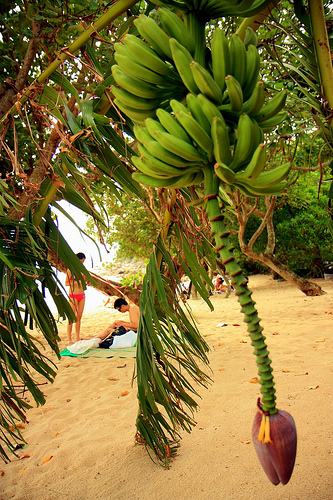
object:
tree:
[0, 0, 333, 319]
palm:
[149, 187, 175, 297]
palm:
[0, 0, 139, 128]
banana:
[154, 130, 208, 166]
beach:
[1, 270, 331, 498]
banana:
[235, 161, 292, 189]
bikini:
[68, 294, 85, 302]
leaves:
[194, 374, 206, 381]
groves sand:
[0, 275, 333, 498]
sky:
[124, 131, 135, 143]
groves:
[249, 377, 258, 383]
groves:
[272, 332, 279, 335]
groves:
[41, 455, 53, 465]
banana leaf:
[131, 187, 219, 471]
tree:
[225, 0, 326, 297]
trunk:
[245, 247, 323, 295]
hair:
[114, 298, 128, 310]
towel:
[67, 337, 102, 355]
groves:
[219, 368, 225, 370]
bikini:
[69, 274, 85, 280]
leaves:
[307, 385, 319, 391]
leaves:
[316, 339, 325, 343]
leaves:
[107, 377, 119, 381]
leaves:
[81, 100, 105, 149]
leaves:
[26, 77, 73, 135]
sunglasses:
[118, 307, 121, 312]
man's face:
[116, 304, 126, 312]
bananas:
[211, 115, 233, 163]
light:
[50, 198, 119, 268]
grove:
[67, 398, 72, 402]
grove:
[117, 363, 127, 367]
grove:
[64, 364, 70, 368]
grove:
[121, 390, 130, 395]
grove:
[218, 343, 225, 347]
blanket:
[55, 330, 189, 358]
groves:
[281, 369, 291, 373]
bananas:
[229, 113, 254, 169]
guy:
[95, 298, 139, 349]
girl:
[65, 252, 86, 344]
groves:
[54, 431, 58, 436]